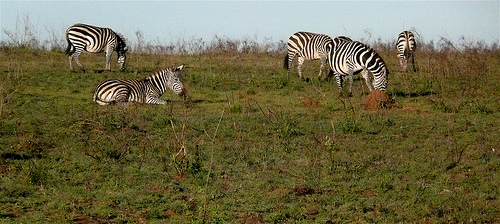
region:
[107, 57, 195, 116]
zebra laying down in the grass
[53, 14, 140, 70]
zebra eating some grass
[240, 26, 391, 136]
two zebras eating grass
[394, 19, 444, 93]
the back end of a zebra eating grass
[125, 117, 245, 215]
several sticks in front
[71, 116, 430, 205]
lots of grass and small shrubs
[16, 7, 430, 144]
many zebras eating grass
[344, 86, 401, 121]
brown shrub in the grass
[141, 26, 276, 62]
lots of dead sticks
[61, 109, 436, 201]
large pasture of grass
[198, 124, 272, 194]
The grass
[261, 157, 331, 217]
The grass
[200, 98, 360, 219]
The grass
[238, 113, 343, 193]
The grass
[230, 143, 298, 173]
The grass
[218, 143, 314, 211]
The grass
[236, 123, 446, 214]
The grass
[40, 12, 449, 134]
five zebras in a field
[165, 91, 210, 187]
tall dried out twigs sticking out the ground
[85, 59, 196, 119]
zebra laying in a field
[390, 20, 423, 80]
butt end of a zebra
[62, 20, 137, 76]
zebra with a big belly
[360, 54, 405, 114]
zebra head behind a dirt pile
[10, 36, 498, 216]
field of brown and green grass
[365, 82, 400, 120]
a brown dirt pile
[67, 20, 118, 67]
stripes that curve in toward the belly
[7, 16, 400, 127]
four zebra's facing right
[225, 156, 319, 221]
The ground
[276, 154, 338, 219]
The ground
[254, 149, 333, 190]
The ground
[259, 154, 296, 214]
The ground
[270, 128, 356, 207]
The ground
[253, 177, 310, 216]
The ground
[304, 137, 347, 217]
The ground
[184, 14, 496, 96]
the zebra has stripes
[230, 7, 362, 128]
the zebra has stripes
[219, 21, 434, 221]
the zebra has stripes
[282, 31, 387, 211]
the zebra has stripes